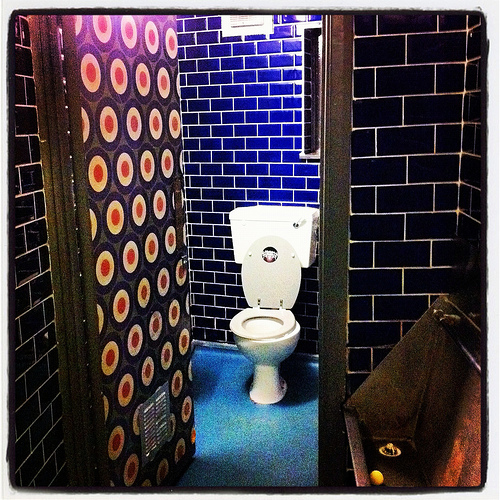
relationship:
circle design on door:
[151, 192, 167, 219] [61, 12, 196, 490]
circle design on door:
[137, 149, 155, 181] [61, 12, 196, 490]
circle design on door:
[159, 228, 179, 255] [61, 12, 196, 490]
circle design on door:
[140, 229, 160, 266] [61, 12, 196, 490]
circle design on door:
[117, 235, 139, 271] [61, 12, 196, 490]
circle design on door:
[123, 108, 143, 141] [61, 12, 196, 490]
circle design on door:
[144, 107, 166, 142] [61, 12, 196, 490]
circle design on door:
[134, 60, 149, 101] [61, 12, 196, 490]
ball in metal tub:
[358, 461, 396, 490] [342, 294, 482, 487]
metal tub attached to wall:
[335, 293, 484, 488] [453, 11, 489, 338]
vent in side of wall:
[140, 380, 168, 469] [179, 20, 316, 350]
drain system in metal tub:
[374, 440, 402, 460] [342, 294, 482, 487]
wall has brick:
[179, 20, 316, 350] [218, 55, 245, 68]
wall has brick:
[179, 20, 316, 350] [280, 97, 302, 106]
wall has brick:
[179, 20, 316, 350] [208, 98, 233, 110]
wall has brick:
[179, 20, 316, 350] [218, 139, 248, 151]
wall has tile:
[179, 20, 316, 350] [212, 176, 233, 189]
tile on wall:
[196, 129, 243, 195] [186, 18, 310, 497]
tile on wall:
[230, 95, 262, 112] [179, 20, 316, 350]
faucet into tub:
[427, 300, 461, 331] [344, 345, 475, 494]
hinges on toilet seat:
[278, 298, 283, 310] [239, 236, 301, 308]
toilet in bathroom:
[227, 205, 320, 405] [71, 13, 322, 487]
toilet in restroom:
[227, 205, 320, 405] [176, 20, 325, 492]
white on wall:
[219, 15, 276, 39] [179, 20, 316, 350]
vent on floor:
[137, 380, 173, 466] [173, 349, 318, 489]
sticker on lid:
[260, 243, 279, 263] [241, 235, 302, 308]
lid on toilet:
[237, 229, 304, 314] [222, 202, 323, 409]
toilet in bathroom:
[222, 202, 323, 409] [71, 13, 322, 487]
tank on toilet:
[227, 204, 318, 268] [228, 233, 301, 404]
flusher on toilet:
[288, 214, 309, 231] [222, 202, 323, 409]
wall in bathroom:
[179, 20, 316, 350] [14, 15, 464, 475]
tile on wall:
[212, 176, 233, 189] [179, 20, 316, 350]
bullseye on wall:
[138, 142, 161, 190] [179, 20, 316, 350]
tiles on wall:
[349, 27, 481, 77] [179, 20, 316, 350]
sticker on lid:
[262, 248, 279, 263] [241, 232, 302, 309]